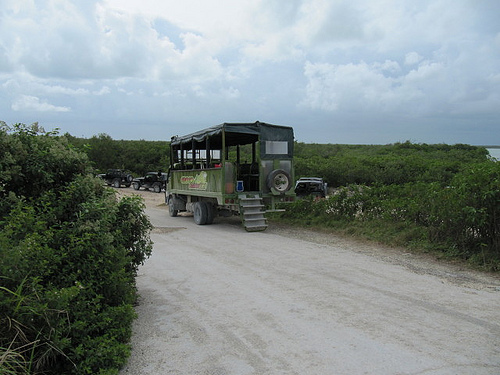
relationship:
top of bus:
[168, 119, 295, 161] [163, 118, 298, 233]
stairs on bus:
[238, 192, 268, 232] [163, 120, 296, 233]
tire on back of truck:
[268, 168, 293, 198] [148, 107, 310, 230]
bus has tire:
[163, 120, 296, 233] [192, 202, 215, 222]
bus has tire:
[163, 120, 296, 233] [269, 167, 292, 196]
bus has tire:
[163, 120, 296, 233] [166, 192, 181, 216]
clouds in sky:
[2, 0, 499, 146] [1, 0, 498, 145]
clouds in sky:
[2, 0, 229, 112] [1, 0, 498, 145]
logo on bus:
[178, 168, 208, 190] [163, 120, 296, 233]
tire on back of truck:
[192, 201, 215, 225] [144, 114, 304, 243]